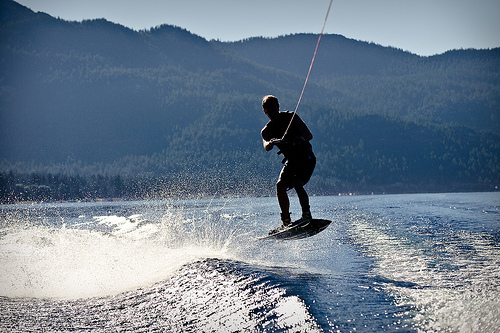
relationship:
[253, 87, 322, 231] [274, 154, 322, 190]
person wearing shorts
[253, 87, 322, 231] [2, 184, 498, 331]
person in water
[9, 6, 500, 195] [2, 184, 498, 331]
moutain behind water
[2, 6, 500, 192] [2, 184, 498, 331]
vegetation behind water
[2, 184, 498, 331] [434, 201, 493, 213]
water has sunlight reflection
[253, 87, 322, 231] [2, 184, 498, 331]
person surfing on water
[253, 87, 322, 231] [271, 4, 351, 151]
person holding string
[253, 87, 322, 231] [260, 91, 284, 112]
person has hair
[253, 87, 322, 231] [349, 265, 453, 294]
person has shadow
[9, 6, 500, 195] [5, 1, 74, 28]
mountain has top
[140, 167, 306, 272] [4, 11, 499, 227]
water droplets spraying in air